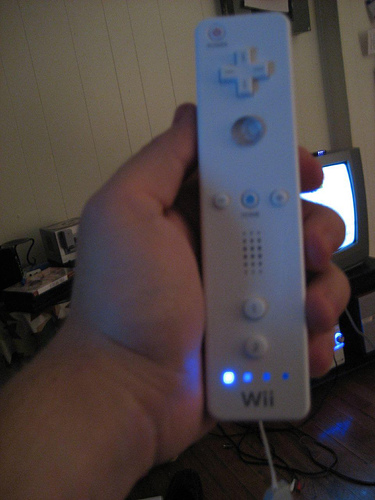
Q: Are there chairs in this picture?
A: No, there are no chairs.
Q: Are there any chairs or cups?
A: No, there are no chairs or cups.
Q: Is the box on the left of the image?
A: Yes, the box is on the left of the image.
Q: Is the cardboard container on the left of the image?
A: Yes, the box is on the left of the image.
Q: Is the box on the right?
A: No, the box is on the left of the image.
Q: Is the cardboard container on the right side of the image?
A: No, the box is on the left of the image.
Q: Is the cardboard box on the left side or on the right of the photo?
A: The box is on the left of the image.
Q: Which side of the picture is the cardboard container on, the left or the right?
A: The box is on the left of the image.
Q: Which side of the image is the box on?
A: The box is on the left of the image.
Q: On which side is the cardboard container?
A: The box is on the left of the image.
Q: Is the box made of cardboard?
A: Yes, the box is made of cardboard.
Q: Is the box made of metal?
A: No, the box is made of cardboard.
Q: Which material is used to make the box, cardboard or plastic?
A: The box is made of cardboard.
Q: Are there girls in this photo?
A: No, there are no girls.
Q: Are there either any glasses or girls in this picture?
A: No, there are no girls or glasses.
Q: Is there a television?
A: Yes, there is a television.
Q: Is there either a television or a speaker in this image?
A: Yes, there is a television.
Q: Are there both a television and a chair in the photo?
A: No, there is a television but no chairs.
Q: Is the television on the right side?
A: Yes, the television is on the right of the image.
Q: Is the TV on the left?
A: No, the TV is on the right of the image.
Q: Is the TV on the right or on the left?
A: The TV is on the right of the image.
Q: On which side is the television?
A: The television is on the right of the image.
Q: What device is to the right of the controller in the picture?
A: The device is a television.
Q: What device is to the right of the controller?
A: The device is a television.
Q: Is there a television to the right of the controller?
A: Yes, there is a television to the right of the controller.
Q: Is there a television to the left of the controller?
A: No, the television is to the right of the controller.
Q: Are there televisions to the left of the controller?
A: No, the television is to the right of the controller.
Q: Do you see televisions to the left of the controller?
A: No, the television is to the right of the controller.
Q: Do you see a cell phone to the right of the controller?
A: No, there is a television to the right of the controller.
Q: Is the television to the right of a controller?
A: Yes, the television is to the right of a controller.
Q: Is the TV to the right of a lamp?
A: No, the TV is to the right of a controller.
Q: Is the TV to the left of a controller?
A: No, the TV is to the right of a controller.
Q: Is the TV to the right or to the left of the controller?
A: The TV is to the right of the controller.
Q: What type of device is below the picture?
A: The device is a television.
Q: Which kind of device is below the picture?
A: The device is a television.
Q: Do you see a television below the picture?
A: Yes, there is a television below the picture.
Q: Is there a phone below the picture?
A: No, there is a television below the picture.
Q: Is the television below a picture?
A: Yes, the television is below a picture.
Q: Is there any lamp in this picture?
A: No, there are no lamps.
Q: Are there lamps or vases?
A: No, there are no lamps or vases.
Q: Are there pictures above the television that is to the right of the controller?
A: Yes, there is a picture above the TV.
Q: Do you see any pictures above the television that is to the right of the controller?
A: Yes, there is a picture above the TV.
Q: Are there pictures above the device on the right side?
A: Yes, there is a picture above the TV.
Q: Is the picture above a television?
A: Yes, the picture is above a television.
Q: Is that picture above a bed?
A: No, the picture is above a television.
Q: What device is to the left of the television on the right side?
A: The device is a controller.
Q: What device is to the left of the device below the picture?
A: The device is a controller.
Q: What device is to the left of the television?
A: The device is a controller.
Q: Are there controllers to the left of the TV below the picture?
A: Yes, there is a controller to the left of the television.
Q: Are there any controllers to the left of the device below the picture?
A: Yes, there is a controller to the left of the television.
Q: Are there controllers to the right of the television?
A: No, the controller is to the left of the television.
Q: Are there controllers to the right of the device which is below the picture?
A: No, the controller is to the left of the television.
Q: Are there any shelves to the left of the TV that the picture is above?
A: No, there is a controller to the left of the television.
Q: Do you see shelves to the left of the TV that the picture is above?
A: No, there is a controller to the left of the television.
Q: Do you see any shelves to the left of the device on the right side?
A: No, there is a controller to the left of the television.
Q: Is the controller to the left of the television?
A: Yes, the controller is to the left of the television.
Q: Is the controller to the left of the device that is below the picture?
A: Yes, the controller is to the left of the television.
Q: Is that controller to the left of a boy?
A: No, the controller is to the left of the television.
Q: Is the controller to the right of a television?
A: No, the controller is to the left of a television.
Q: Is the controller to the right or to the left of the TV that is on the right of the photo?
A: The controller is to the left of the television.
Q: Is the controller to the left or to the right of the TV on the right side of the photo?
A: The controller is to the left of the television.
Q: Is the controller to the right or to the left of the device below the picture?
A: The controller is to the left of the television.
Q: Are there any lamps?
A: No, there are no lamps.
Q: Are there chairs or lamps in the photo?
A: No, there are no lamps or chairs.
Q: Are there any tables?
A: Yes, there is a table.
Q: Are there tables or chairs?
A: Yes, there is a table.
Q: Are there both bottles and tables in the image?
A: No, there is a table but no bottles.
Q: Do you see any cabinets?
A: No, there are no cabinets.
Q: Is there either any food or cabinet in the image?
A: No, there are no cabinets or food.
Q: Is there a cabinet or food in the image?
A: No, there are no cabinets or food.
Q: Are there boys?
A: No, there are no boys.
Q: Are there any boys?
A: No, there are no boys.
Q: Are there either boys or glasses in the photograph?
A: No, there are no boys or glasses.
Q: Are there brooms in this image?
A: No, there are no brooms.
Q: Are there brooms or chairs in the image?
A: No, there are no brooms or chairs.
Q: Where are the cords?
A: The cords are on the floor.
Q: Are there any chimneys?
A: No, there are no chimneys.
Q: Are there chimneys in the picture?
A: No, there are no chimneys.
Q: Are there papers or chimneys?
A: No, there are no chimneys or papers.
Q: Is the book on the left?
A: Yes, the book is on the left of the image.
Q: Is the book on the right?
A: No, the book is on the left of the image.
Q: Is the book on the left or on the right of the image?
A: The book is on the left of the image.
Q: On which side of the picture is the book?
A: The book is on the left of the image.